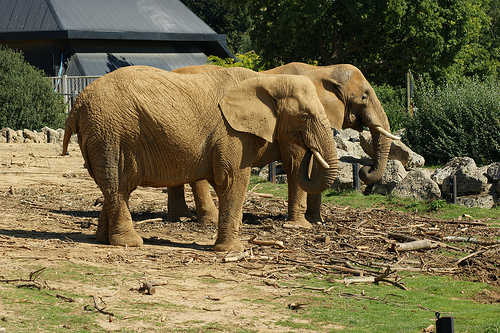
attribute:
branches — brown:
[324, 206, 487, 277]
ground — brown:
[2, 194, 499, 326]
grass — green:
[11, 254, 487, 332]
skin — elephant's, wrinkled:
[93, 75, 203, 187]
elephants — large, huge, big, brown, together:
[71, 67, 394, 255]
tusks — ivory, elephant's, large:
[311, 148, 330, 171]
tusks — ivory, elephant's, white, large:
[378, 126, 402, 145]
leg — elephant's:
[220, 181, 245, 252]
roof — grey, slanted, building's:
[3, 1, 228, 59]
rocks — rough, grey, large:
[389, 146, 497, 207]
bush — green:
[411, 77, 499, 161]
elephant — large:
[325, 62, 394, 190]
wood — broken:
[295, 208, 475, 316]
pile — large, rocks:
[341, 133, 497, 206]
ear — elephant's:
[216, 70, 277, 146]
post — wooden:
[348, 162, 362, 191]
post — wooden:
[451, 177, 457, 202]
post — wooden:
[267, 163, 278, 182]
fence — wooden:
[45, 77, 104, 114]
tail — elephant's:
[58, 109, 77, 157]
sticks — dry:
[248, 193, 497, 284]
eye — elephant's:
[298, 112, 311, 121]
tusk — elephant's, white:
[307, 146, 335, 173]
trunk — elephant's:
[296, 144, 336, 191]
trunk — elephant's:
[357, 118, 396, 187]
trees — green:
[232, 0, 499, 62]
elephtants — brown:
[55, 68, 396, 253]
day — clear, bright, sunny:
[2, 3, 498, 327]